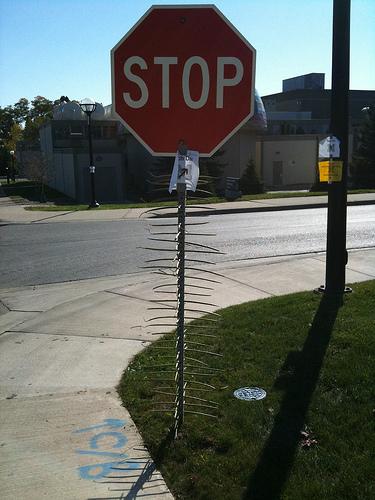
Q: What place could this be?
A: It is a sidewalk.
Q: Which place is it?
A: It is a sidewalk.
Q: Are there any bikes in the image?
A: No, there are no bikes.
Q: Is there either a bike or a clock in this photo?
A: No, there are no bikes or clocks.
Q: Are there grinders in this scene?
A: No, there are no grinders.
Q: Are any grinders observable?
A: No, there are no grinders.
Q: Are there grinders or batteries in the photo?
A: No, there are no grinders or batteries.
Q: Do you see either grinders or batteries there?
A: No, there are no grinders or batteries.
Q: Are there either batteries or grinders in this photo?
A: No, there are no grinders or batteries.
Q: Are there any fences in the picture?
A: No, there are no fences.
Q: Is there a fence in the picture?
A: No, there are no fences.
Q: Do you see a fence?
A: No, there are no fences.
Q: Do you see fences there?
A: No, there are no fences.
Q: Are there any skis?
A: No, there are no skis.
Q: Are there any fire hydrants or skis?
A: No, there are no skis or fire hydrants.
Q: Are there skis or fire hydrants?
A: No, there are no skis or fire hydrants.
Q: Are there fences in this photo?
A: No, there are no fences.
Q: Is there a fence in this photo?
A: No, there are no fences.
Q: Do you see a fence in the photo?
A: No, there are no fences.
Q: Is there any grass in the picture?
A: Yes, there is grass.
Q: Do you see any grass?
A: Yes, there is grass.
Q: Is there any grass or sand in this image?
A: Yes, there is grass.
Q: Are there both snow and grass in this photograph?
A: No, there is grass but no snow.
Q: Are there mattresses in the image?
A: No, there are no mattresses.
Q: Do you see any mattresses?
A: No, there are no mattresses.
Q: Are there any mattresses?
A: No, there are no mattresses.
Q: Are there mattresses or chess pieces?
A: No, there are no mattresses or chess pieces.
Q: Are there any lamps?
A: Yes, there is a lamp.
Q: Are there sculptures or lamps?
A: Yes, there is a lamp.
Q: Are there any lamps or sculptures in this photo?
A: Yes, there is a lamp.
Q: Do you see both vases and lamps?
A: No, there is a lamp but no vases.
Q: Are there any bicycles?
A: No, there are no bicycles.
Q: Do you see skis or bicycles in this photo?
A: No, there are no bicycles or skis.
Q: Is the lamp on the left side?
A: Yes, the lamp is on the left of the image.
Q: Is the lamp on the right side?
A: No, the lamp is on the left of the image.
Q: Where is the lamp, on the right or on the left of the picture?
A: The lamp is on the left of the image.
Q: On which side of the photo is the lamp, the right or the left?
A: The lamp is on the left of the image.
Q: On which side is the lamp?
A: The lamp is on the left of the image.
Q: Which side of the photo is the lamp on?
A: The lamp is on the left of the image.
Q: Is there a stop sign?
A: Yes, there is a stop sign.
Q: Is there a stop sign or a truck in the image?
A: Yes, there is a stop sign.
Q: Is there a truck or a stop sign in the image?
A: Yes, there is a stop sign.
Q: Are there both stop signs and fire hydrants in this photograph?
A: No, there is a stop sign but no fire hydrants.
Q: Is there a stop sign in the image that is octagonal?
A: Yes, there is an octagonal stop sign.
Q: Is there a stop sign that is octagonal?
A: Yes, there is a stop sign that is octagonal.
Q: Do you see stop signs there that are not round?
A: Yes, there is a octagonal stop sign.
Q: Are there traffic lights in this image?
A: No, there are no traffic lights.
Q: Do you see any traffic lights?
A: No, there are no traffic lights.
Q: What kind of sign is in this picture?
A: The sign is a stop sign.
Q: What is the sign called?
A: The sign is a stop sign.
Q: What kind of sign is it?
A: The sign is a stop sign.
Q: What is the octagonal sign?
A: The sign is a stop sign.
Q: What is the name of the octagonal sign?
A: The sign is a stop sign.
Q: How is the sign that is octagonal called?
A: The sign is a stop sign.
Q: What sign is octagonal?
A: The sign is a stop sign.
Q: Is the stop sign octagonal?
A: Yes, the stop sign is octagonal.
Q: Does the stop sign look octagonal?
A: Yes, the stop sign is octagonal.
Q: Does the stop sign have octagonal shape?
A: Yes, the stop sign is octagonal.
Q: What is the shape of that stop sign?
A: The stop sign is octagonal.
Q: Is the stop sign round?
A: No, the stop sign is octagonal.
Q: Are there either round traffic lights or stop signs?
A: No, there is a stop sign but it is octagonal.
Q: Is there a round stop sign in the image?
A: No, there is a stop sign but it is octagonal.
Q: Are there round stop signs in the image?
A: No, there is a stop sign but it is octagonal.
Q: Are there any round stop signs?
A: No, there is a stop sign but it is octagonal.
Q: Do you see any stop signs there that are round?
A: No, there is a stop sign but it is octagonal.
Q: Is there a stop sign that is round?
A: No, there is a stop sign but it is octagonal.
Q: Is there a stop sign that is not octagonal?
A: No, there is a stop sign but it is octagonal.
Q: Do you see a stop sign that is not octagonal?
A: No, there is a stop sign but it is octagonal.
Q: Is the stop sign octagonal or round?
A: The stop sign is octagonal.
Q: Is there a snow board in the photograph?
A: No, there are no snowboards.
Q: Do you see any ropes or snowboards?
A: No, there are no snowboards or ropes.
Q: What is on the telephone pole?
A: The paper is on the utility pole.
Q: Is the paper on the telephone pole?
A: Yes, the paper is on the telephone pole.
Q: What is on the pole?
A: The paper is on the pole.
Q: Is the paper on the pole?
A: Yes, the paper is on the pole.